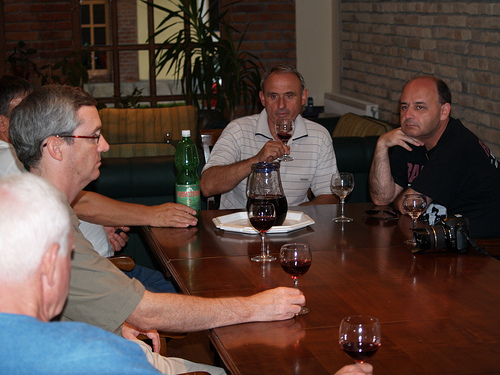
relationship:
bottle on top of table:
[171, 127, 206, 223] [147, 192, 499, 370]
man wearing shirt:
[0, 95, 314, 368] [69, 237, 142, 331]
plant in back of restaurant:
[140, 0, 297, 100] [6, 2, 496, 372]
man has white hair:
[0, 167, 215, 375] [0, 170, 69, 292]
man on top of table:
[367, 70, 497, 255] [146, 211, 498, 338]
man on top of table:
[202, 65, 347, 207] [146, 211, 498, 338]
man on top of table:
[6, 81, 308, 329] [146, 211, 498, 338]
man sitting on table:
[367, 70, 497, 255] [147, 192, 499, 370]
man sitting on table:
[202, 65, 347, 207] [147, 192, 499, 370]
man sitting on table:
[0, 95, 314, 368] [147, 192, 499, 370]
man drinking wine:
[367, 70, 497, 255] [271, 117, 296, 165]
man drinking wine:
[202, 65, 347, 207] [271, 117, 296, 165]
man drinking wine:
[0, 167, 215, 375] [271, 117, 296, 165]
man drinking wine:
[0, 95, 314, 368] [271, 117, 296, 165]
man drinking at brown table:
[367, 70, 497, 255] [136, 188, 499, 370]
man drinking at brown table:
[202, 65, 347, 207] [136, 188, 499, 370]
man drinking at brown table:
[6, 81, 308, 329] [136, 188, 499, 370]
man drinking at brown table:
[4, 167, 215, 372] [136, 188, 499, 370]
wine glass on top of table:
[331, 170, 356, 224] [147, 192, 499, 370]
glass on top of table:
[400, 191, 424, 245] [147, 192, 499, 370]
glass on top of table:
[280, 244, 312, 316] [147, 192, 499, 370]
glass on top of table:
[334, 310, 383, 363] [147, 192, 499, 370]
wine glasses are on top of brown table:
[246, 166, 434, 361] [136, 188, 499, 370]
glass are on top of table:
[334, 310, 383, 363] [137, 197, 495, 363]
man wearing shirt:
[0, 167, 215, 375] [0, 313, 162, 373]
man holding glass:
[0, 167, 215, 375] [335, 312, 390, 369]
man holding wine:
[4, 167, 215, 372] [340, 332, 384, 357]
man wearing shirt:
[6, 81, 308, 329] [19, 168, 145, 337]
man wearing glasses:
[6, 81, 308, 353] [39, 126, 103, 146]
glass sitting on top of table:
[246, 196, 284, 265] [147, 192, 499, 370]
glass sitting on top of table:
[334, 310, 383, 363] [147, 192, 499, 370]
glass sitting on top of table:
[280, 244, 312, 316] [147, 192, 499, 370]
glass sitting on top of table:
[400, 191, 424, 245] [147, 192, 499, 370]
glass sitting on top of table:
[331, 172, 357, 227] [147, 192, 499, 370]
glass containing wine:
[246, 196, 284, 265] [246, 214, 276, 230]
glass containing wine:
[280, 244, 312, 316] [277, 256, 311, 275]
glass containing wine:
[334, 310, 383, 363] [339, 340, 380, 360]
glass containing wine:
[400, 191, 424, 245] [401, 203, 426, 218]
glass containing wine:
[331, 172, 357, 227] [328, 183, 355, 196]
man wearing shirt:
[202, 65, 347, 207] [198, 107, 343, 217]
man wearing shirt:
[367, 70, 497, 255] [390, 124, 499, 241]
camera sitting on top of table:
[403, 208, 496, 260] [146, 203, 485, 372]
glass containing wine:
[331, 172, 357, 227] [330, 181, 355, 200]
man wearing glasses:
[6, 81, 308, 353] [35, 127, 104, 154]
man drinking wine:
[202, 65, 347, 207] [276, 130, 292, 145]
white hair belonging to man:
[0, 170, 69, 292] [7, 167, 172, 373]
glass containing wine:
[280, 244, 312, 316] [281, 259, 309, 272]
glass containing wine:
[334, 310, 383, 363] [343, 340, 379, 361]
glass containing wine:
[246, 196, 284, 265] [248, 217, 280, 232]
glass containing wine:
[273, 114, 294, 162] [271, 107, 296, 162]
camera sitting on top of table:
[409, 209, 486, 256] [147, 192, 499, 370]